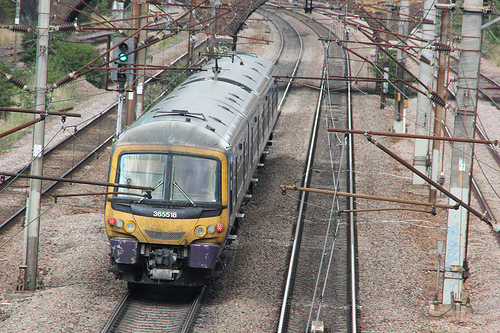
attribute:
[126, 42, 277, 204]
train roof — tan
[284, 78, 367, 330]
track — metal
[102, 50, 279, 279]
train — old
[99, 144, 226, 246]
train — yellow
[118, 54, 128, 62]
light — green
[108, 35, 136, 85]
light — green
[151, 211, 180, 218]
number — white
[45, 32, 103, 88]
shrubs — green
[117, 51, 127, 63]
traffic light — green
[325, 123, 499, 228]
poles — rusted, angled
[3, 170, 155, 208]
poles — rusted, angled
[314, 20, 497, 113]
poles — rusted, angled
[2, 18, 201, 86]
poles — rusted, angled